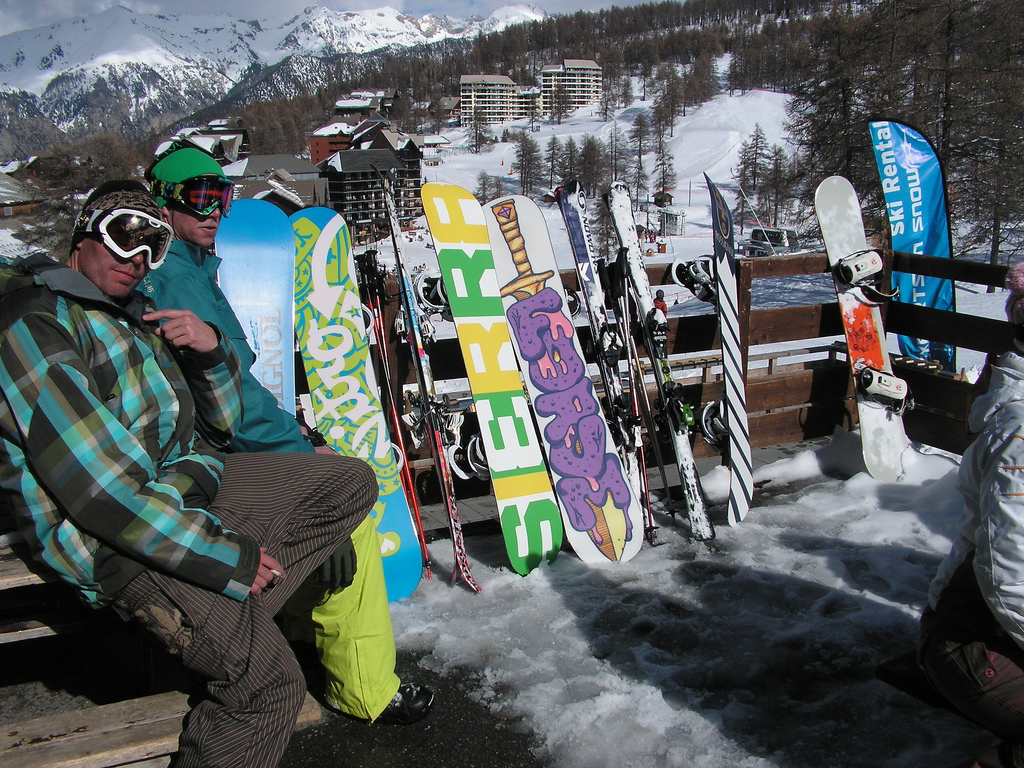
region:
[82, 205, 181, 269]
black and white goggles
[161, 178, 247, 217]
green and red goggles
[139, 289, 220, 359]
left hand on man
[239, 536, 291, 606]
right hand of the man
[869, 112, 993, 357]
blue ski rental sign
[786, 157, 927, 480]
white and red snow board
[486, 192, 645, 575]
purple and white surfboard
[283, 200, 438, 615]
blue and green surfboard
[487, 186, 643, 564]
the purple white and gold snowboard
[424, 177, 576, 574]
the green and yellow snowboard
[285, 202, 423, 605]
the green and yellow snowboard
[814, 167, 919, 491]
the grey red and white snowboard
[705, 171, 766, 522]
the black and white snowboard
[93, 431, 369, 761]
the brown snow pants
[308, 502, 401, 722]
the yellow snow pants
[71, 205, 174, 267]
the snowboarding goggles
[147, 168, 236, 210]
the snowboarding goggles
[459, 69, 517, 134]
the tall building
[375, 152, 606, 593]
The snowboard is white green and yellow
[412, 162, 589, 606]
The snowboard has letters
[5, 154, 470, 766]
The boy is wearing blue flannel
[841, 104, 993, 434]
The sign is blue with white letters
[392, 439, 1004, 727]
Snow is on the ground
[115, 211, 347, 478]
The boy is wearing a blue coat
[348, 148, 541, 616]
The skis are red and blue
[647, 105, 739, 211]
Snow is white color.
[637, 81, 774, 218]
Snow is in ground.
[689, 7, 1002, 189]
Pine trees are behind the fence.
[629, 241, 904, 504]
Fence is brown color.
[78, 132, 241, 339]
Two men are wearing goggles in eyes.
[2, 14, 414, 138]
Mountains are seen behind the person.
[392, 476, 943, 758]
Shadow falls on the ground.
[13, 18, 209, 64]
Mountains are covered with snow.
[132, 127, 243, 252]
Man is wearing green cap.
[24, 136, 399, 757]
People wearing their goggles.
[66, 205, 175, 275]
A pair of black snowboarding goggles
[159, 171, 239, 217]
A pair of red snowboarding goggles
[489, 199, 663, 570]
Snowboard with purple writing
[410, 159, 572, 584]
Snowboard with yellow and green writing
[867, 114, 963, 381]
Blue sign for advertising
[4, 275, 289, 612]
Plaid teal and black coat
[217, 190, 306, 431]
Blue snowboard with gray writing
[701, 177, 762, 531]
Snowboard with white and black stripes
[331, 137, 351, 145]
building has a window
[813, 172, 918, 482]
A board used for snowboarding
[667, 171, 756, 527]
A board used for snowboarding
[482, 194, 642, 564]
A board used for snowboarding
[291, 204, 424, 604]
A board used for snowboarding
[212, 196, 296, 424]
A board used for snowboarding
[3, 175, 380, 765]
A person is sitting on a bench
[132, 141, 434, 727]
A person is sitting on a bench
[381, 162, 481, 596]
A ski used for skiing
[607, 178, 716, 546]
A ski used for skiing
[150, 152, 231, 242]
man wearing a green winter hat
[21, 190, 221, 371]
a man pointing his finger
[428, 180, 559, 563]
yellow and green snowboard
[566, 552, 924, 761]
shadows being cast in the snow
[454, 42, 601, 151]
buildings on a mountain side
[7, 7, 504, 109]
snow on a mountain side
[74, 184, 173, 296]
man wearing black and white goggles